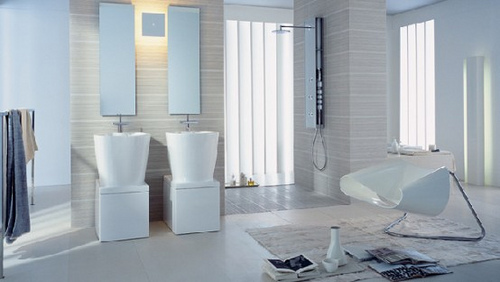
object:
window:
[399, 19, 434, 149]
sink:
[166, 131, 220, 182]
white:
[97, 2, 134, 117]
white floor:
[193, 266, 234, 281]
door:
[222, 18, 295, 188]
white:
[30, 28, 66, 98]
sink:
[93, 131, 152, 186]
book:
[261, 253, 321, 281]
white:
[174, 131, 213, 228]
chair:
[338, 159, 486, 242]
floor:
[172, 233, 270, 269]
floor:
[0, 238, 154, 282]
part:
[259, 213, 269, 222]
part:
[230, 227, 253, 255]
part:
[241, 256, 257, 268]